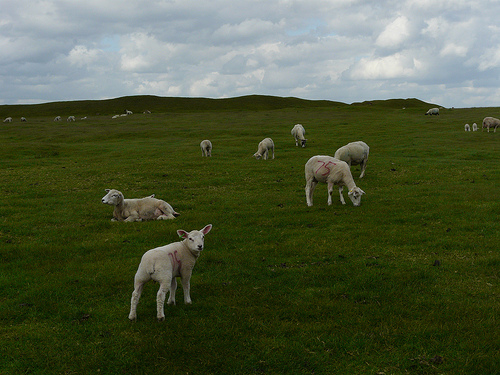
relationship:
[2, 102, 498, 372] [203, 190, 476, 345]
grass on ground